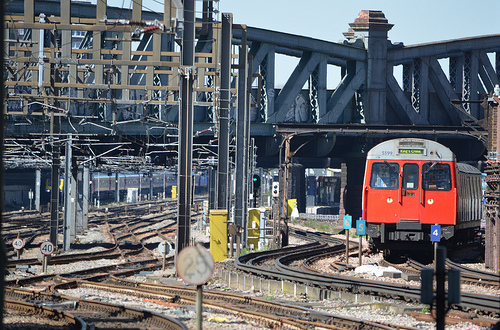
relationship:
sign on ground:
[175, 242, 216, 285] [2, 286, 499, 329]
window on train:
[369, 162, 401, 190] [362, 136, 484, 256]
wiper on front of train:
[380, 160, 399, 178] [362, 136, 484, 256]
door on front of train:
[399, 162, 421, 223] [362, 136, 484, 256]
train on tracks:
[362, 136, 484, 256] [233, 220, 499, 320]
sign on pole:
[175, 242, 216, 285] [193, 285, 204, 329]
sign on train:
[399, 148, 425, 156] [362, 136, 484, 256]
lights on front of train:
[387, 194, 392, 204] [362, 136, 484, 256]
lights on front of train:
[426, 197, 436, 207] [362, 136, 484, 256]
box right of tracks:
[208, 210, 230, 260] [233, 220, 499, 320]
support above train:
[178, 0, 195, 251] [362, 136, 484, 256]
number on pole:
[431, 226, 441, 242] [433, 245, 439, 263]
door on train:
[399, 162, 421, 223] [362, 136, 484, 256]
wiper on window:
[380, 160, 399, 178] [369, 162, 401, 190]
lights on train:
[387, 194, 392, 204] [362, 136, 484, 256]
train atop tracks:
[362, 136, 484, 256] [233, 220, 499, 320]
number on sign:
[431, 226, 441, 242] [175, 242, 216, 285]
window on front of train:
[369, 162, 401, 190] [362, 136, 484, 256]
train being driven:
[362, 136, 484, 256] [427, 167, 448, 189]